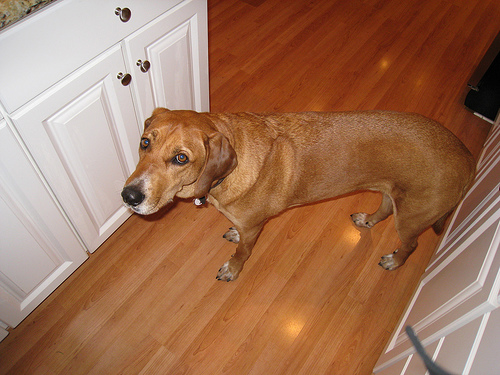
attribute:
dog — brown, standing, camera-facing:
[115, 101, 478, 276]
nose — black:
[119, 183, 149, 209]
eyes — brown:
[135, 133, 197, 166]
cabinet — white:
[0, 2, 241, 367]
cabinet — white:
[367, 122, 498, 371]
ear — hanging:
[183, 122, 241, 199]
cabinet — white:
[0, 3, 209, 348]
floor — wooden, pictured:
[2, 5, 499, 365]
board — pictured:
[189, 203, 332, 373]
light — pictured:
[280, 310, 311, 349]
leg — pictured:
[209, 215, 254, 286]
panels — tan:
[18, 202, 221, 368]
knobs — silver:
[115, 3, 155, 86]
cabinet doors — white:
[13, 6, 209, 277]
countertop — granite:
[3, 1, 18, 15]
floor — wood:
[201, 283, 263, 334]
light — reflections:
[336, 229, 356, 246]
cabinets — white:
[441, 245, 481, 304]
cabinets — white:
[440, 244, 478, 340]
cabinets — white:
[443, 227, 482, 290]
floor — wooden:
[255, 302, 333, 346]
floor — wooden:
[271, 279, 363, 350]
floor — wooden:
[277, 282, 369, 368]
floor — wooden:
[290, 283, 352, 363]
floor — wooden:
[272, 260, 355, 350]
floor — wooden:
[290, 280, 369, 364]